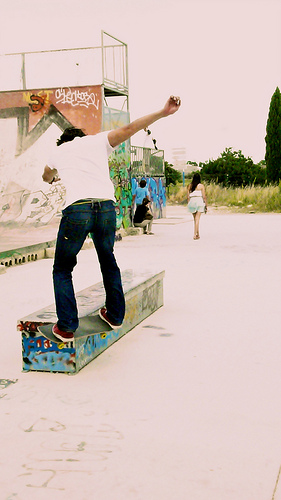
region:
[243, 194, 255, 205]
patch of green grass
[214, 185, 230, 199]
patch of green grass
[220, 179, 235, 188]
patch of green grass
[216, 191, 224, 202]
patch of green grass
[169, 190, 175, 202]
patch of green grass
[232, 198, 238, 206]
patch of green grass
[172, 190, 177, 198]
patch of green grass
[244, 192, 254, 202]
patch of green grass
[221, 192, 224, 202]
patch of green grass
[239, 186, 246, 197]
patch of green grass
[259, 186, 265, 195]
patch of green grass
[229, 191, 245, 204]
patch of green grass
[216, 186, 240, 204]
patch of green grass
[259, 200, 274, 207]
patch of green grass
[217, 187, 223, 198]
patch of green grass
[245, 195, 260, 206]
patch of green grass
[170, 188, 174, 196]
patch of green grass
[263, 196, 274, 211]
patch of green grass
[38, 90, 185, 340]
the man is skateboarding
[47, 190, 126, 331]
man is wearing blue jeans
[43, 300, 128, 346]
man's shoes are red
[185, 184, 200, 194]
woman's shirt is white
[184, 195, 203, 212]
woman wearing a skirt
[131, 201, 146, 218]
man's shirt is black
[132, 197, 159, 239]
man is sitting down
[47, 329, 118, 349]
skateboard wheels are yellow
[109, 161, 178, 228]
graffiti on the wall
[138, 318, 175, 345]
black stains on ground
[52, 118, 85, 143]
hair of a person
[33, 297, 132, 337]
feet of a person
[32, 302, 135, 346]
a pair of red sneakers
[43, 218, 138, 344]
legs of a person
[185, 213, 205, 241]
legs of a person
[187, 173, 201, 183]
head of a person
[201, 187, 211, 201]
arm of a person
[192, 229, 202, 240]
feet of a person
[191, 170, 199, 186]
hair of a person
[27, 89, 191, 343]
person on his skateboard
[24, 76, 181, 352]
man doing trick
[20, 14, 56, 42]
white clouds in blue sky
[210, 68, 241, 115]
white clouds in blue sky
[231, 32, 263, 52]
white clouds in blue sky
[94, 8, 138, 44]
white clouds in blue sky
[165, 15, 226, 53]
white clouds in blue sky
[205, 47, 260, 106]
white clouds in blue sky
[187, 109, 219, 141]
white clouds in blue sky